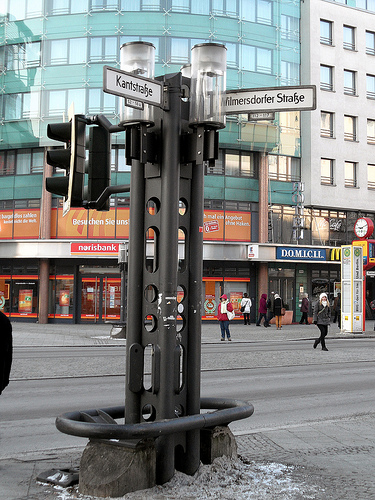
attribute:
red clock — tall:
[354, 218, 372, 235]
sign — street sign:
[101, 58, 188, 117]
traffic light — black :
[34, 112, 92, 219]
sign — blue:
[213, 82, 322, 116]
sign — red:
[72, 241, 121, 255]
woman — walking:
[313, 290, 334, 344]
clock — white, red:
[352, 216, 372, 237]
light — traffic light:
[39, 117, 77, 194]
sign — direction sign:
[99, 62, 170, 113]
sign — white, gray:
[203, 71, 326, 142]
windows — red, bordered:
[0, 271, 122, 324]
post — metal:
[160, 129, 181, 234]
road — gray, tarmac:
[223, 347, 364, 380]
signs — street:
[99, 60, 317, 114]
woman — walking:
[313, 293, 332, 351]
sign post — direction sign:
[204, 83, 317, 116]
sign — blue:
[273, 243, 339, 265]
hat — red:
[217, 291, 228, 303]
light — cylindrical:
[186, 37, 228, 124]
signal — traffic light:
[41, 114, 122, 212]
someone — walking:
[307, 288, 335, 349]